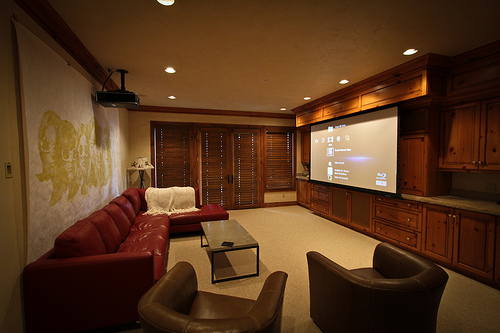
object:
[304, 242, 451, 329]
chair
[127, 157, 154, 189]
lamp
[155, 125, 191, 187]
window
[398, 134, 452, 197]
ground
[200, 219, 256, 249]
glass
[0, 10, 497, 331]
room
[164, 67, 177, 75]
light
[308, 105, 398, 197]
projector screen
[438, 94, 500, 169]
cabinet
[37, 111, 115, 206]
animals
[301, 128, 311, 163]
cabinets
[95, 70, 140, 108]
projector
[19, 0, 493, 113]
ceiling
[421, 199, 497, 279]
cabinets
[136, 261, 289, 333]
arm chairs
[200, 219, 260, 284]
coffee table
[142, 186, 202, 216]
blanket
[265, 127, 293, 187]
blinds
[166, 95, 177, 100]
light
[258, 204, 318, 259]
floor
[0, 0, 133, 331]
wall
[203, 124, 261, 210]
doors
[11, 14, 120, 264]
tapestry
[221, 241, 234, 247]
control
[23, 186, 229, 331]
couch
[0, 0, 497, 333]
living room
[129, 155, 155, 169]
lamp shade